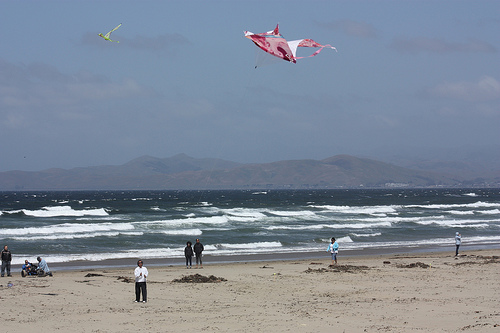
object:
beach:
[0, 249, 500, 330]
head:
[137, 260, 143, 268]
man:
[132, 259, 148, 304]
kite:
[243, 22, 340, 66]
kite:
[98, 23, 123, 44]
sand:
[0, 250, 500, 333]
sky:
[0, 0, 499, 172]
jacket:
[325, 242, 340, 255]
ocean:
[0, 186, 500, 274]